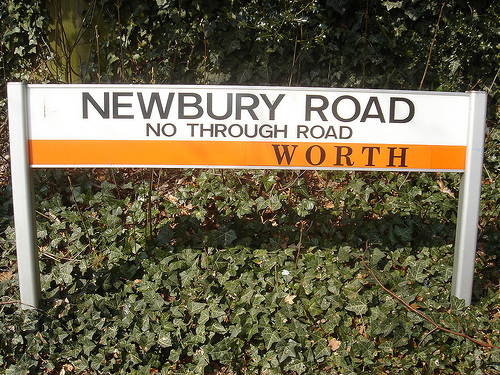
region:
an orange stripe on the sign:
[20, 135, 468, 169]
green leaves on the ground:
[2, 187, 494, 374]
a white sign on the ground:
[7, 78, 487, 335]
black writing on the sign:
[75, 85, 427, 169]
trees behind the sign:
[3, 2, 498, 88]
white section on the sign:
[17, 85, 477, 147]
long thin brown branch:
[353, 248, 492, 348]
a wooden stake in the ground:
[5, 75, 42, 305]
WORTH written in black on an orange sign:
[274, 142, 418, 172]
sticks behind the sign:
[34, 7, 101, 81]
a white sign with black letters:
[22, 76, 470, 178]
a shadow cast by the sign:
[70, 203, 455, 313]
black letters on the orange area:
[255, 142, 440, 179]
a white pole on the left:
[0, 74, 50, 329]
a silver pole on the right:
[461, 79, 496, 331]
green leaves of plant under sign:
[50, 197, 486, 371]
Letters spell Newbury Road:
[74, 84, 428, 121]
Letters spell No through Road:
[140, 117, 375, 144]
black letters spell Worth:
[258, 144, 418, 180]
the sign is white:
[26, 80, 475, 205]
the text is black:
[86, 88, 451, 183]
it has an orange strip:
[2, 130, 479, 192]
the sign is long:
[10, 58, 492, 248]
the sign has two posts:
[17, 65, 494, 327]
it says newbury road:
[75, 73, 447, 121]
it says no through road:
[140, 119, 360, 143]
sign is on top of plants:
[7, 203, 399, 329]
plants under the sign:
[18, 171, 458, 366]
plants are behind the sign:
[0, 13, 460, 154]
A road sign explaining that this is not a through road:
[5, 76, 489, 316]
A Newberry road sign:
[1, 79, 483, 321]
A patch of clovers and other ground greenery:
[117, 208, 346, 356]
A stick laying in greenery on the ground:
[349, 237, 464, 358]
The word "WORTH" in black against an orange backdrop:
[267, 139, 410, 170]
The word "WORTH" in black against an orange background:
[272, 143, 409, 172]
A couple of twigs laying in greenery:
[260, 206, 437, 361]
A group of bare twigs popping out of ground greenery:
[64, 177, 221, 291]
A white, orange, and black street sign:
[5, 74, 484, 317]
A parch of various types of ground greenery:
[73, 240, 317, 367]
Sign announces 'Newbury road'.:
[71, 90, 416, 122]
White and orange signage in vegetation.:
[12, 83, 485, 173]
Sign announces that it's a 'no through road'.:
[147, 123, 350, 143]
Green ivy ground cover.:
[94, 213, 385, 370]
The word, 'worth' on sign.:
[271, 143, 411, 173]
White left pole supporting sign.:
[4, 80, 41, 315]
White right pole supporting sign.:
[455, 88, 485, 311]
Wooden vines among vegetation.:
[63, 177, 166, 250]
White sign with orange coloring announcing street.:
[9, 78, 485, 318]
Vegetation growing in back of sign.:
[110, 3, 485, 80]